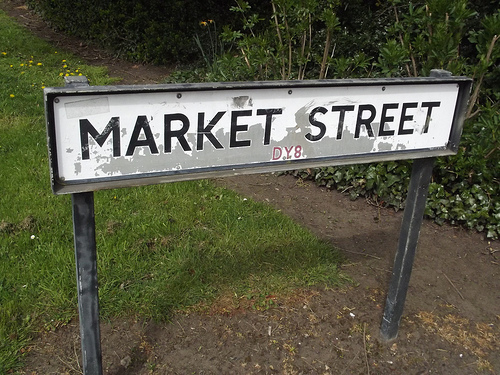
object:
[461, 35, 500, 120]
branches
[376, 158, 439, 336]
black pole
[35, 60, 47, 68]
yellow flowers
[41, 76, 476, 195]
sign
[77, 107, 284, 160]
word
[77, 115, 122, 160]
letter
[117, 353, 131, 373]
rock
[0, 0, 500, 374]
ground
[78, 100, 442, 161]
market street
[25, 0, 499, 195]
trees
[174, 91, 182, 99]
bolt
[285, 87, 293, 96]
bolt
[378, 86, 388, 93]
bolt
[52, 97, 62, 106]
bolt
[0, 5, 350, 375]
grass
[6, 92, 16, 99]
flowers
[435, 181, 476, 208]
leaves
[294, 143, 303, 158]
number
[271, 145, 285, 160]
red letter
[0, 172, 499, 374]
dirt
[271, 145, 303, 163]
dy8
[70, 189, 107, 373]
poles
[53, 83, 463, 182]
paint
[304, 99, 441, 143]
writing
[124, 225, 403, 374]
shadow